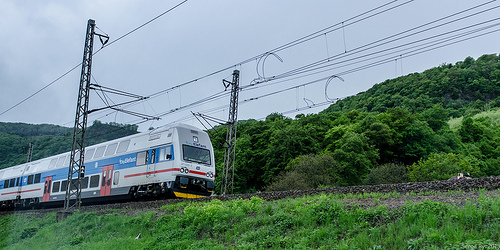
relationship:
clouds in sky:
[23, 25, 96, 75] [124, 34, 247, 74]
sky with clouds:
[124, 34, 247, 74] [23, 25, 96, 75]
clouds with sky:
[23, 25, 96, 75] [124, 34, 247, 74]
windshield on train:
[181, 149, 221, 173] [73, 133, 217, 198]